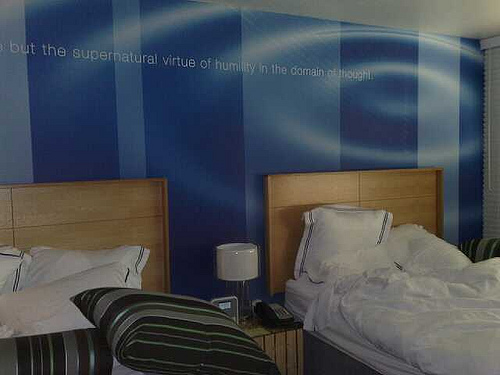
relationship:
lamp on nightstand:
[215, 240, 259, 320] [238, 308, 303, 374]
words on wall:
[8, 37, 372, 81] [0, 3, 483, 313]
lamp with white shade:
[215, 240, 259, 320] [214, 242, 259, 281]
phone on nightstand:
[249, 299, 294, 328] [238, 308, 303, 374]